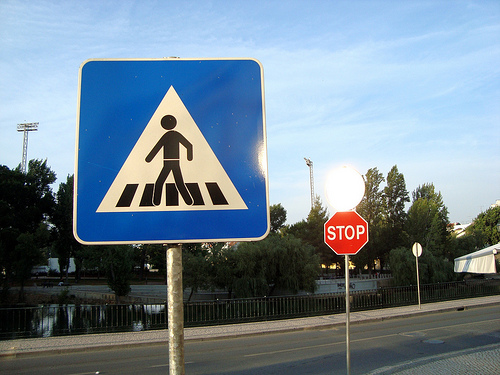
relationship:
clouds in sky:
[144, 17, 449, 59] [1, 0, 498, 222]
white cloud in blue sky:
[460, 145, 495, 179] [249, 0, 428, 39]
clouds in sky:
[0, 0, 499, 222] [1, 0, 498, 222]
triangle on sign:
[95, 83, 250, 214] [65, 50, 275, 250]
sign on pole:
[65, 50, 275, 250] [163, 245, 197, 373]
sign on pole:
[320, 205, 373, 257] [341, 252, 355, 372]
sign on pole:
[409, 237, 424, 256] [413, 257, 425, 311]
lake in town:
[0, 297, 480, 342] [20, 300, 169, 340]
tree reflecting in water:
[239, 226, 342, 293] [45, 297, 212, 339]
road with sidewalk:
[14, 295, 498, 369] [9, 287, 489, 354]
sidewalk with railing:
[0, 289, 499, 357] [2, 275, 499, 336]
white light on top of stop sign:
[318, 162, 365, 210] [323, 209, 367, 373]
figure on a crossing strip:
[114, 113, 228, 207] [95, 160, 236, 221]